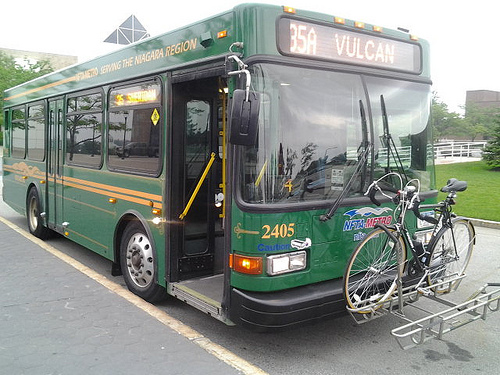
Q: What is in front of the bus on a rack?
A: Bike.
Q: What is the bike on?
A: Rack.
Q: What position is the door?
A: Open.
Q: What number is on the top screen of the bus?
A: 35.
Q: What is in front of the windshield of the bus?
A: Bike.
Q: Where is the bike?
A: On a rack.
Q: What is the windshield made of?
A: Glass.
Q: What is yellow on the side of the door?
A: Handle.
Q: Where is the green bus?
A: On the street.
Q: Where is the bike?
A: Front of bus.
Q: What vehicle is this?
A: Bus.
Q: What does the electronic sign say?
A: Vulcan.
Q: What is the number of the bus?
A: 2405.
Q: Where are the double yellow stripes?
A: On the bus.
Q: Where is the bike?
A: On bike rack.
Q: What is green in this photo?
A: The bus.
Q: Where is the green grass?
A: Behind bus.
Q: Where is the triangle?
A: Above bus.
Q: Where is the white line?
A: On road.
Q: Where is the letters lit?
A: On front of bus.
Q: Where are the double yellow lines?
A: On side of bus.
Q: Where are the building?
A: Background.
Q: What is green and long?
A: The bus.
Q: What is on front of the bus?
A: A bicycle.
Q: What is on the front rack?
A: A bike.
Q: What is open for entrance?
A: The bus doors.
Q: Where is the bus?
A: On the street.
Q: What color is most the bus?
A: Green.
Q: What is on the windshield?
A: Wipers.